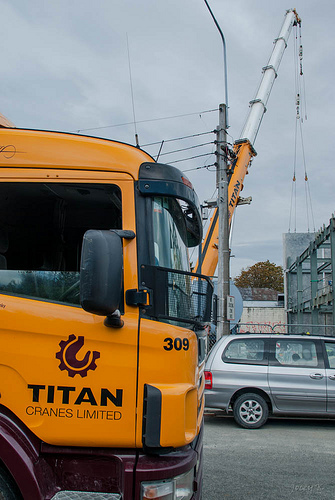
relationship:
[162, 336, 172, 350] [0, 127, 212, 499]
number 3 on truck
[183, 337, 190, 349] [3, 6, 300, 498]
number 9 on truck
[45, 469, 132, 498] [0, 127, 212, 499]
step on truck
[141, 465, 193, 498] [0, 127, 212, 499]
headlight on truck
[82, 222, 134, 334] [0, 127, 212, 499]
mirror on truck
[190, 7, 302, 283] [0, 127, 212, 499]
crane behind truck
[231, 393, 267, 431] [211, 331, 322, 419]
tire on van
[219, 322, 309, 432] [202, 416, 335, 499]
car on asphalt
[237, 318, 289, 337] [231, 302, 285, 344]
graffiti on wall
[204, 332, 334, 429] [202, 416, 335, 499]
car on asphalt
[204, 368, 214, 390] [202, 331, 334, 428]
taillight on back of car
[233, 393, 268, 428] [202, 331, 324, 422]
tire on car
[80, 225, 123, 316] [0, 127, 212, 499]
mirror on truck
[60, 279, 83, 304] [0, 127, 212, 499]
steering wheel inside truck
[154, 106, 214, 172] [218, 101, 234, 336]
lines coming off pole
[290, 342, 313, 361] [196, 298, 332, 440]
seats in car